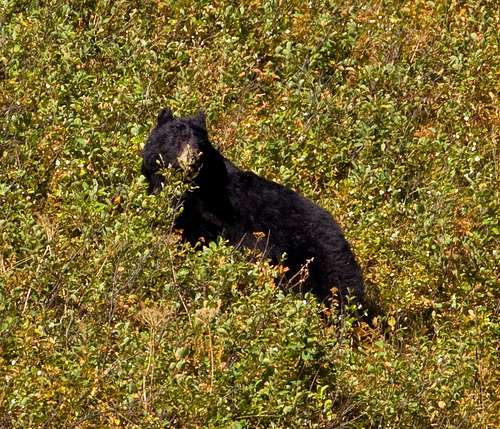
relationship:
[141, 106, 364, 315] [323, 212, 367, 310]
bear has rear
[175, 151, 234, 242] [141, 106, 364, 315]
shadow cast on bear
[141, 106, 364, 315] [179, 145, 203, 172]
bear has snout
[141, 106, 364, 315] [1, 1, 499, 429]
bear among leaves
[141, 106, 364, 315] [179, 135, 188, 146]
bear has eye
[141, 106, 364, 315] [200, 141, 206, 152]
bear has eye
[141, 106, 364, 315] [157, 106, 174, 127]
bear has ear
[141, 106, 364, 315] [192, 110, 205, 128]
bear has ear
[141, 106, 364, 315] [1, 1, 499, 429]
bear sitting among leaves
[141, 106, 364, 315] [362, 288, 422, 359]
bear has shadow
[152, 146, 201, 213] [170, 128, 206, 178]
branch covering face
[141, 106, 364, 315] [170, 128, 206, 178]
bear has face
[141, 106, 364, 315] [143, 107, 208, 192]
bear has head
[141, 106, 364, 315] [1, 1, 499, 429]
bear running in leaves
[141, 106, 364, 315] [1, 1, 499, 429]
bear in leaves